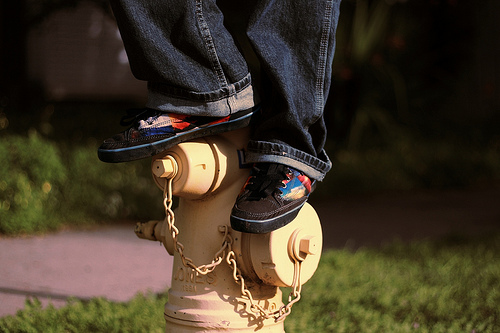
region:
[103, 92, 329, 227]
His shoes are black.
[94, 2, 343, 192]
The pants are jeans.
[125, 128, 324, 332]
The fire hydrant is yellow.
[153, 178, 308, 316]
A chain is on the fire hydrant.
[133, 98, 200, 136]
His shoes have a red design.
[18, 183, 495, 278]
The sidewalk is gray.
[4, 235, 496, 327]
The grass is green.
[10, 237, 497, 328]
The grass is growing.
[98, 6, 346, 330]
He is standing on the fire hydrant.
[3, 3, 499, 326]
The sun is shining.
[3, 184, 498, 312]
an empty sidewalk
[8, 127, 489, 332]
grass on both sides of the sidewalk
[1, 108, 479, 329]
the grass is a nice green color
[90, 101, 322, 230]
sneakers being used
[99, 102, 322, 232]
the sneakers are black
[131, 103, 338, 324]
a fire hydrant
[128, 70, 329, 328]
the fire hydrant is tan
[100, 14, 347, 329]
a person is standing on the fire hydrant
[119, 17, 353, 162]
jean pants being worn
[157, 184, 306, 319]
chains on the fire hydrant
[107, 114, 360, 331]
light yellow fire hydrant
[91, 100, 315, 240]
black tennis shoes with red and blue design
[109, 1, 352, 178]
dark blue jeans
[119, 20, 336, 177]
dark jeans with rolled cuffs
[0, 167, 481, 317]
cement sidewalk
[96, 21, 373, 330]
person standing on a fire hydrant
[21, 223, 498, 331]
lawn with green grass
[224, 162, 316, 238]
shoe with black laces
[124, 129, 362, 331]
fire hydrant with a chain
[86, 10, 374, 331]
black shoes on a hydrant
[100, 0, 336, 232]
person balancing on fire hydrant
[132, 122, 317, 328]
fire hydrant is painted yellow for visibility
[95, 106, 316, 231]
kid wearing converse shoes plays on hydrant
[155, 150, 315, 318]
chain connected to both sides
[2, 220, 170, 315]
grey sidewalk behind person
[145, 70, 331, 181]
pants are rolled up to prevent getting dirty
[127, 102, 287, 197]
black shoe laces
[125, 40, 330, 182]
wearing dark colored pants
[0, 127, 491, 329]
grass isnt in focus for picture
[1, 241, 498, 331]
grass surrounding hydrant is dark green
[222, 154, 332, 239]
Black tennis shoe strings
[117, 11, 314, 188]
Denim jeans with cuff rolled up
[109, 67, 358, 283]
Person on hydrant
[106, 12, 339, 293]
Person standing on fire hydrant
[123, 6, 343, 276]
Person standing on yellow hydrant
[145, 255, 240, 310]
yellow hydrant with JONES on it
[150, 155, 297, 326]
yellow chain on fire hydrant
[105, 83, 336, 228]
Pair of colorful tennis shoes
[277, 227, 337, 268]
bolt on fire hydrant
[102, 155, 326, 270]
three bolts on fire hydrant